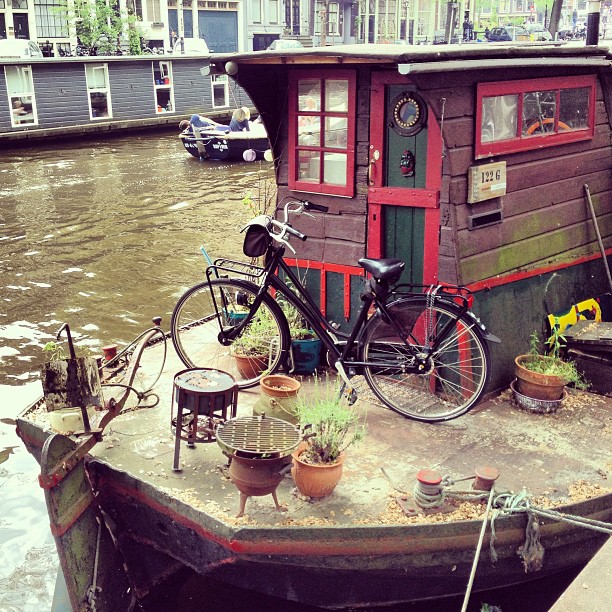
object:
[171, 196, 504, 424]
bicycle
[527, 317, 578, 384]
pottedplant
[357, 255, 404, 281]
seat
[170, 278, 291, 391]
tire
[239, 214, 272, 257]
bag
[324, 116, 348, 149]
glass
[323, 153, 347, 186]
glass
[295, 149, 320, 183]
glass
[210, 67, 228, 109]
glass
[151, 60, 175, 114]
glass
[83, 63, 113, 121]
glass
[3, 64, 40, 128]
glass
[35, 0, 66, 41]
glass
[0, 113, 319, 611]
water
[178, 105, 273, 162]
boat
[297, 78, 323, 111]
glass